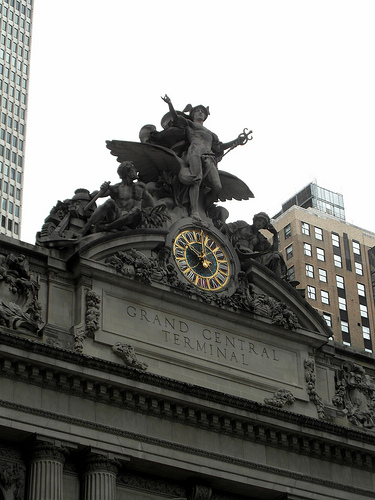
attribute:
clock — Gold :
[158, 218, 250, 296]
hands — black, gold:
[182, 227, 213, 268]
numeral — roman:
[212, 246, 228, 261]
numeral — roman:
[217, 258, 230, 275]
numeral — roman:
[208, 276, 221, 291]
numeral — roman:
[182, 266, 198, 283]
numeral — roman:
[173, 244, 187, 257]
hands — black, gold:
[189, 229, 209, 259]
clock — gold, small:
[170, 221, 234, 297]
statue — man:
[129, 89, 252, 231]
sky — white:
[202, 11, 360, 105]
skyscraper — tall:
[0, 0, 36, 240]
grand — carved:
[122, 302, 190, 336]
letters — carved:
[118, 306, 293, 376]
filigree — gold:
[176, 231, 231, 292]